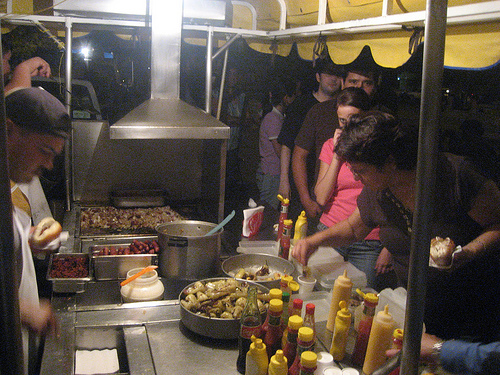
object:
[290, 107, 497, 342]
woman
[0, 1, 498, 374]
stand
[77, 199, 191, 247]
grill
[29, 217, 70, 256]
hot dog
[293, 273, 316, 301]
cup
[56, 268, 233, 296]
stove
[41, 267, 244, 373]
surface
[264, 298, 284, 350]
bottle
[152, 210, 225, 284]
pot of food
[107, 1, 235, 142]
ventilation system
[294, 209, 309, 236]
bottle of mustard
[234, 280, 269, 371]
bottle of coke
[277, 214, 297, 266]
bottle of ketchup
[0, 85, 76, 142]
black baseball cap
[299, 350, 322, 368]
small yellow lid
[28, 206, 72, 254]
hot dog bun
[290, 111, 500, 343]
woman eating food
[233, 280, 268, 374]
bottle of coca cola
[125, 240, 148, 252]
array of condiments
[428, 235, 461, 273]
woman's hot dog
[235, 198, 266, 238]
napkins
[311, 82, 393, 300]
girl in pink shirt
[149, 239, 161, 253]
cooked hot dogs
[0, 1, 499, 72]
yellow awning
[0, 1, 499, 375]
hot dog stand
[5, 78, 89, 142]
man in black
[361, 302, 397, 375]
plastic bottles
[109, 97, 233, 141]
fan hood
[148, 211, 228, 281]
large soup pan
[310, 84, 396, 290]
young girl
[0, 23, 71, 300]
guy holding hot dog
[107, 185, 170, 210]
food on the grill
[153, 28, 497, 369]
line of people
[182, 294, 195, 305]
veggies in a pot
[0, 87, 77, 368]
guy dipping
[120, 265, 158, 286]
large orange spoon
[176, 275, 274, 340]
circular white bowl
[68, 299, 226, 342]
line on silver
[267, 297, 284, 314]
yellow lid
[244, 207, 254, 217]
white paper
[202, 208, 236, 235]
edge of blue utensil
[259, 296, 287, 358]
large red ketchup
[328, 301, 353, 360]
condiment bottles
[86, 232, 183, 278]
pan of hotdogs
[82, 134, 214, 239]
cooking on a grill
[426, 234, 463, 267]
hotdog bun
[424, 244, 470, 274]
paper sleeve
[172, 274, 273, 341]
pan full of potatoes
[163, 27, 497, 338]
people waiting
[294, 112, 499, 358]
woman in brown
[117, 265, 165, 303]
jar of mayonnaise